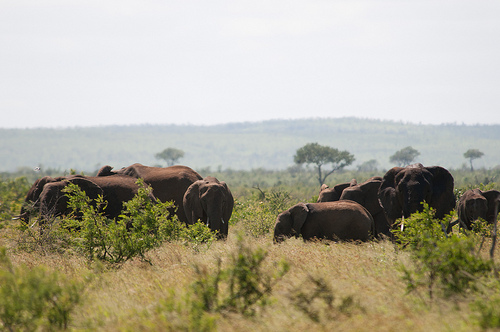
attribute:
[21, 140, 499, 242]
elephants — herd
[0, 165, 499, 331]
desert — landscape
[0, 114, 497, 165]
horizon — flat, wide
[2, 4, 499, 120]
sky — cloudy, blue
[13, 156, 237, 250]
elephants — smaller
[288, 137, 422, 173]
trees — short, around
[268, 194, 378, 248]
elephant — young, small, baby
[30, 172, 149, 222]
elephant — adult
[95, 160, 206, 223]
elephant — brown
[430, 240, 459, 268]
leaves — green